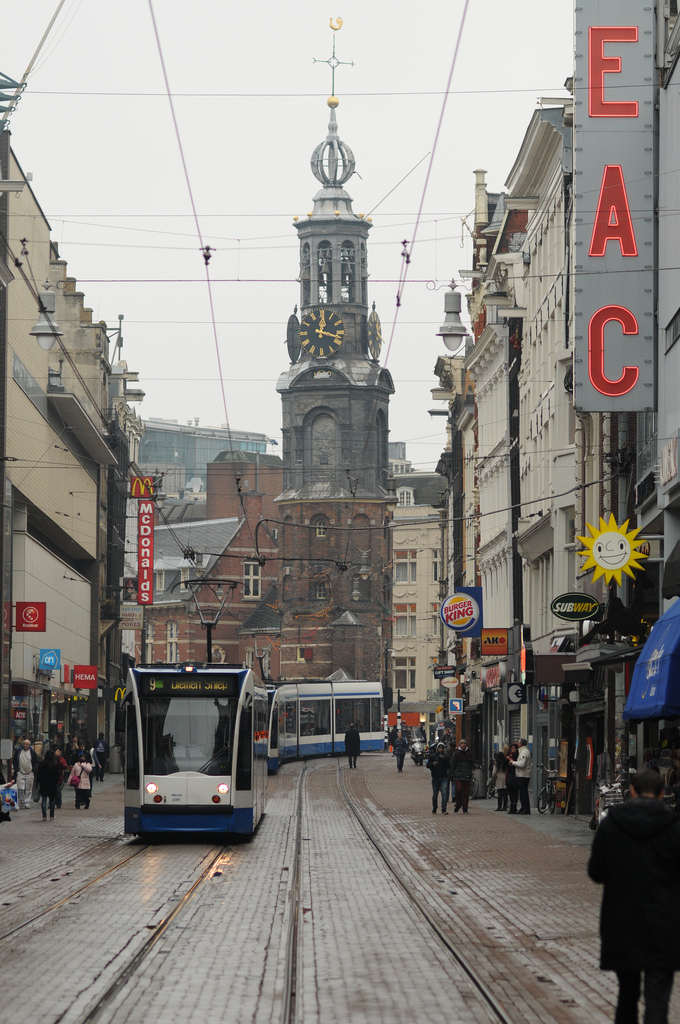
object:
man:
[448, 738, 476, 815]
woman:
[83, 739, 103, 798]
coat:
[513, 746, 534, 779]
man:
[509, 737, 532, 815]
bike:
[536, 762, 566, 815]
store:
[537, 640, 612, 811]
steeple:
[294, 14, 373, 222]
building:
[387, 440, 449, 751]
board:
[136, 672, 238, 696]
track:
[54, 842, 235, 1021]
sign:
[137, 498, 155, 607]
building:
[0, 126, 146, 794]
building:
[277, 53, 398, 764]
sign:
[480, 628, 509, 657]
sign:
[449, 697, 465, 716]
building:
[238, 569, 285, 686]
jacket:
[344, 728, 362, 758]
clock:
[297, 297, 346, 360]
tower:
[272, 194, 394, 387]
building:
[129, 414, 283, 515]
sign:
[112, 683, 127, 703]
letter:
[587, 24, 640, 118]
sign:
[570, 0, 659, 416]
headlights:
[145, 781, 158, 795]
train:
[115, 651, 352, 830]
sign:
[13, 598, 47, 633]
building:
[493, 76, 591, 816]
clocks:
[286, 304, 301, 364]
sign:
[439, 586, 483, 639]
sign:
[549, 591, 600, 623]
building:
[330, 609, 366, 746]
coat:
[585, 796, 680, 977]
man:
[586, 765, 680, 1022]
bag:
[69, 774, 80, 788]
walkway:
[443, 802, 680, 1020]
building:
[449, 165, 528, 805]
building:
[140, 487, 282, 680]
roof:
[153, 516, 244, 602]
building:
[566, 54, 679, 819]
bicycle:
[468, 760, 481, 801]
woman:
[67, 755, 92, 812]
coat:
[66, 761, 93, 789]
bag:
[0, 783, 20, 810]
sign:
[575, 511, 650, 589]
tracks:
[267, 768, 340, 1024]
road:
[257, 807, 569, 1024]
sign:
[503, 682, 528, 705]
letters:
[553, 602, 562, 613]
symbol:
[131, 477, 153, 497]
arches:
[131, 477, 144, 497]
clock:
[367, 300, 383, 362]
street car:
[124, 660, 387, 844]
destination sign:
[171, 678, 228, 691]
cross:
[311, 30, 356, 96]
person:
[491, 751, 509, 812]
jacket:
[392, 738, 407, 756]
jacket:
[492, 761, 508, 791]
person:
[391, 732, 407, 774]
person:
[426, 742, 450, 817]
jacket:
[426, 753, 451, 781]